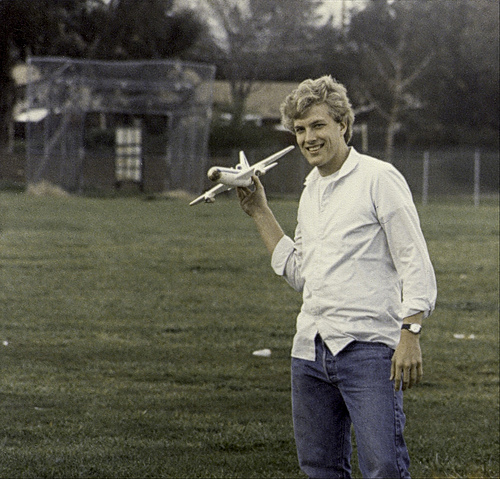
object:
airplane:
[189, 146, 295, 208]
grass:
[1, 191, 498, 478]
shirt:
[268, 147, 437, 361]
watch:
[407, 323, 422, 333]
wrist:
[399, 324, 425, 339]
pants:
[290, 334, 413, 478]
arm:
[236, 173, 305, 291]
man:
[237, 74, 438, 478]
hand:
[390, 337, 423, 389]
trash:
[252, 349, 272, 358]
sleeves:
[392, 236, 439, 315]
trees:
[1, 1, 500, 193]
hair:
[280, 74, 353, 144]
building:
[26, 60, 210, 196]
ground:
[1, 190, 499, 479]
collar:
[303, 146, 360, 185]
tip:
[209, 167, 220, 179]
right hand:
[239, 175, 267, 214]